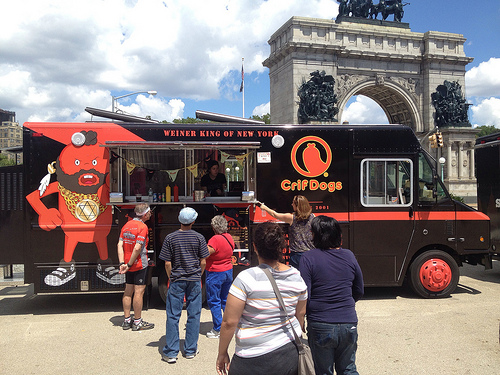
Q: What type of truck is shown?
A: Food truck.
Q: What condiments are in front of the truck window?
A: Ketchup and mustard.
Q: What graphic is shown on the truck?
A: Caricature of Mr. T.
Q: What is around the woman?
A: Purse.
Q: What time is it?
A: Afternoon.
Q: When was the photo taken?
A: During the daytime.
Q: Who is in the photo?
A: Some people.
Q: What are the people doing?
A: Walking.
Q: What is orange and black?
A: The van.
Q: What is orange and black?
A: The wheels.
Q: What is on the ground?
A: Dirt.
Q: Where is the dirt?
A: On the ground.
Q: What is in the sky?
A: Clouds.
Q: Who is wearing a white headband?
A: A man.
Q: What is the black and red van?
A: A hot dog restaurant.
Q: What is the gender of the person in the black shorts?
A: Male.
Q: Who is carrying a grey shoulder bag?
A: A woman.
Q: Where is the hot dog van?
A: In a parking lot.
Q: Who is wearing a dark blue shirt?
A: A woman.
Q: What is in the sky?
A: Fluffy white clouds.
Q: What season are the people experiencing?
A: Summer.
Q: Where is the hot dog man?
A: On the truck.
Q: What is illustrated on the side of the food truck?
A: A cartoon.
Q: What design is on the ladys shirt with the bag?
A: Stripes.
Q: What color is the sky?
A: Blue and white.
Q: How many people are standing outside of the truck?
A: Six.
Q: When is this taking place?
A: Daytime.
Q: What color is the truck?
A: Black and red.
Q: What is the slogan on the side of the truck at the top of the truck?
A: Weiner king of new york.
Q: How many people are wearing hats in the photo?
A: One.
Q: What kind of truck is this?
A: Food truck.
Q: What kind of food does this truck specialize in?
A: Hot dogs.